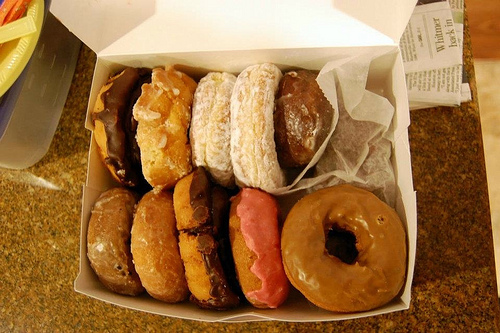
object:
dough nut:
[173, 167, 232, 312]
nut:
[275, 69, 328, 168]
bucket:
[0, 10, 81, 172]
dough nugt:
[132, 63, 198, 186]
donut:
[190, 71, 234, 187]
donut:
[229, 62, 286, 192]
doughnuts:
[229, 62, 284, 191]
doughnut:
[227, 187, 286, 310]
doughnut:
[129, 189, 187, 304]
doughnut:
[83, 185, 143, 298]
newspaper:
[399, 0, 471, 112]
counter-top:
[0, 0, 499, 331]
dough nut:
[187, 72, 234, 187]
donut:
[279, 187, 407, 314]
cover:
[0, 1, 46, 100]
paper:
[278, 60, 396, 205]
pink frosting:
[236, 186, 285, 308]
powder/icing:
[189, 62, 285, 190]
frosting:
[90, 64, 150, 189]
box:
[48, 0, 418, 324]